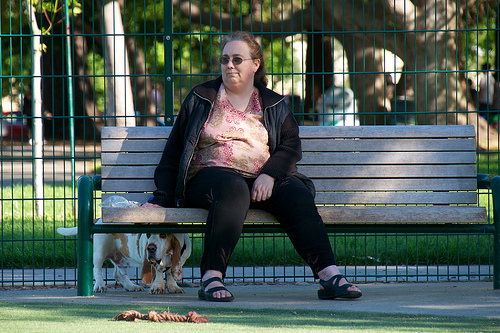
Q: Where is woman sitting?
A: Bench.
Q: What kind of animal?
A: Dog.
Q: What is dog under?
A: Bench.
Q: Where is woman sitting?
A: Bench.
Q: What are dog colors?
A: Brown and white.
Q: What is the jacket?
A: Open.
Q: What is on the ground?
A: Shadows.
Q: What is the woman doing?
A: Sitting on a bench.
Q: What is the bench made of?
A: Wood and metal.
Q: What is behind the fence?
A: A metal fence.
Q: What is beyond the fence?
A: Trees.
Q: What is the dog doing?
A: Hiding under the bench.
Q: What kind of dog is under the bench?
A: A basset hound.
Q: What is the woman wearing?
A: Black jacket, pink and brown shirt, and black pants.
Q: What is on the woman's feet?
A: Sandals.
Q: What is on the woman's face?
A: Sunglasses.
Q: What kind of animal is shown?
A: A dog.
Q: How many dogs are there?
A: One.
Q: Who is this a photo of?
A: A woman.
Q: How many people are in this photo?
A: One.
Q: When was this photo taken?
A: Daytime.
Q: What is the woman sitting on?
A: A bench.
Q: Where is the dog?
A: Under the bench.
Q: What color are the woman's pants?
A: Black.